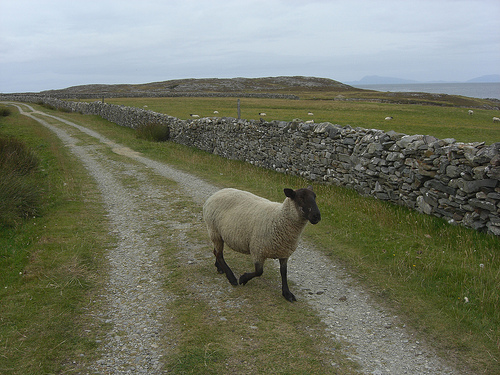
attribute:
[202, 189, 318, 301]
sheep — running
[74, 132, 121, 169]
trail — worn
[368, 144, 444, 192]
wall — stone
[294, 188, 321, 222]
face — black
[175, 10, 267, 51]
skies — gray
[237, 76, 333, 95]
hill — rocky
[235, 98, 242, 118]
post — metal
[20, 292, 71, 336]
grass — green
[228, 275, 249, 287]
feet — black